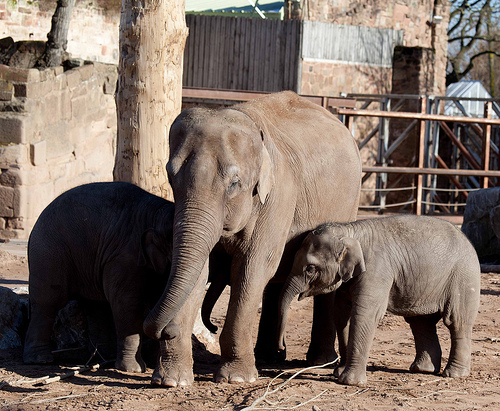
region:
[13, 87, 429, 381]
three elephants standing next to each other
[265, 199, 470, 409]
a baby elephant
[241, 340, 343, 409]
a tree limb on the ground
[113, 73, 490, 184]
metal fencing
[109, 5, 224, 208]
a tree trunk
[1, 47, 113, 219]
a brick wall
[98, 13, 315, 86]
a wooden fence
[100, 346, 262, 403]
a elephants two front feet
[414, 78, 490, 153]
the roof of a building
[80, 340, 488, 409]
dirt ground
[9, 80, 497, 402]
three elephants in a zoo enclosure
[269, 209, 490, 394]
baby elephant next to mom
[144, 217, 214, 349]
trunk of an adult elephant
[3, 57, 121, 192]
stone wall in the background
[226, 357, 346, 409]
tree branches on the ground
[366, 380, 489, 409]
dirt ground where elephants are standing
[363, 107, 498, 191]
fence enclosure behind elephants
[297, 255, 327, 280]
left eye of a baby elephant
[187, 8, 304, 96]
wood picket fence in the background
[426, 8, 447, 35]
light fixture on the building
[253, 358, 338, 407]
long branch on ground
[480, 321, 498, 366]
small stones on the ground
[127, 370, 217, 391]
large hoof on elephant's foot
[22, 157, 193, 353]
shadow of elephant on the ground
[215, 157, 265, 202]
large dark eyes on elephant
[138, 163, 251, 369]
large tusk on elephant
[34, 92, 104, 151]
stones on the compound wall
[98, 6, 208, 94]
large tree trunk in enclosure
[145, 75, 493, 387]
pair of elephant in enclosure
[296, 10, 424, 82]
large silver cover on wall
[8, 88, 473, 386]
Three elephants stand under a tree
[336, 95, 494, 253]
Brown metal bars in the background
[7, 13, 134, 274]
A beige brick wall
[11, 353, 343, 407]
Twigs and branches lie on the ground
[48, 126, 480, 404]
The elephants are standing on dirt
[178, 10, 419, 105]
A wooden planked fence sits on top of the brick wall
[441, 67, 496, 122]
A silver shed with window panes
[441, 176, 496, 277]
A large grey cement rock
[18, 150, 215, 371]
The smaller elephant is in the shade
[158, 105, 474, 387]
The bigger elephant and smaller elephant are in the sun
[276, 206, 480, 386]
Smallest gray elephant to the right of the largest elephant.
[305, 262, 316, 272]
Baby elephants left eye.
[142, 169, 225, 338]
Large trunk of big elephant in the middle.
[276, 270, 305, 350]
Tiny trunk of baby elephant.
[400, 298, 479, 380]
Back legs of a baby elephant.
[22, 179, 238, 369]
Very dark elephant to the left of a large elephant.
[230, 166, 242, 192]
Left eye of a large elephant.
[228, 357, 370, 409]
Thin gray tree branch with no leaves.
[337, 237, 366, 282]
Left ear of a baby gray elephant.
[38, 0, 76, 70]
Gray tree trunk growing out of a block wall.